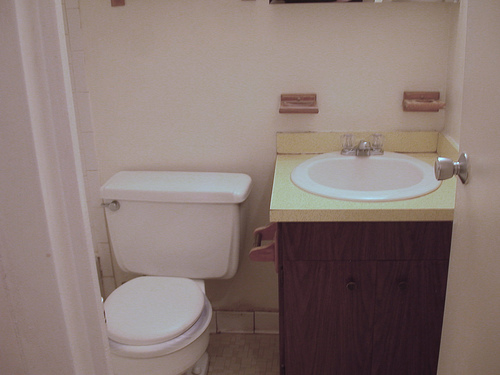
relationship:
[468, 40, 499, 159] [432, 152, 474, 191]
door has knob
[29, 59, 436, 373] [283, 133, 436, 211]
bathroom has sink fixture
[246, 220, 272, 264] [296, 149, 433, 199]
toliet roll attached to sink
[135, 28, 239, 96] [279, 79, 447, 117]
wall has soapdishes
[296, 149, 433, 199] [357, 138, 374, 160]
sink has faucets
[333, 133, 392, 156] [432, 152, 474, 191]
faucet has knob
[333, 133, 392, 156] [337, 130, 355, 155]
faucet has coldwater knob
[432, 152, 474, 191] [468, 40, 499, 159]
knob of door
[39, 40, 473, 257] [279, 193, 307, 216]
bathroom has counter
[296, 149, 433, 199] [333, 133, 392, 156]
sink has faucet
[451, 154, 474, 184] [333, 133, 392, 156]
handle of faucet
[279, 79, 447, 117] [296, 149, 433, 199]
soapdishes on sink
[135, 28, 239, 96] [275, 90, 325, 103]
wall has holders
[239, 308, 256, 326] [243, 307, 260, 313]
tile has mold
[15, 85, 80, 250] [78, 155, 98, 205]
shower has white tile